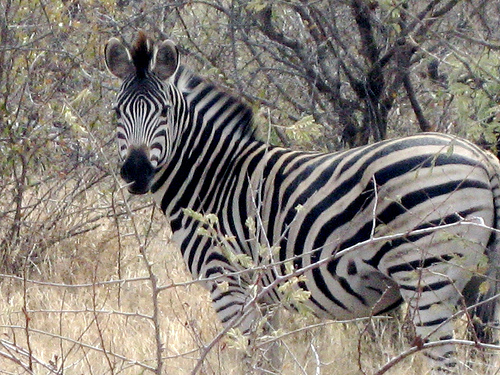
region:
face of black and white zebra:
[88, 37, 201, 216]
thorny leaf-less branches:
[48, 197, 161, 347]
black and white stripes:
[291, 153, 363, 228]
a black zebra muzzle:
[108, 138, 160, 204]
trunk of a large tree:
[283, 5, 410, 152]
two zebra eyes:
[108, 97, 184, 129]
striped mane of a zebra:
[181, 65, 267, 145]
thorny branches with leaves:
[188, 200, 308, 358]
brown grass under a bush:
[33, 213, 133, 295]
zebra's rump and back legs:
[366, 125, 495, 363]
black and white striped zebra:
[101, 35, 498, 369]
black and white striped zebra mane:
[130, 32, 257, 136]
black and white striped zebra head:
[113, 70, 178, 187]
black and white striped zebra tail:
[483, 157, 498, 274]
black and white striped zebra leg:
[196, 262, 262, 374]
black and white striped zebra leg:
[386, 200, 486, 368]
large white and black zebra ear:
[105, 37, 133, 79]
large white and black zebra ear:
[153, 40, 180, 81]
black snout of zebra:
[119, 149, 154, 192]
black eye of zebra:
[159, 104, 171, 117]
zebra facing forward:
[78, 23, 494, 370]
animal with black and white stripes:
[65, 24, 492, 366]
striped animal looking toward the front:
[55, 17, 492, 364]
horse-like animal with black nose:
[70, 22, 498, 362]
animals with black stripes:
[56, 22, 498, 351]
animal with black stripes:
[78, 27, 481, 372]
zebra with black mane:
[84, 27, 494, 367]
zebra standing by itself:
[79, 25, 496, 361]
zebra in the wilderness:
[62, 31, 499, 362]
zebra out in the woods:
[65, 31, 488, 372]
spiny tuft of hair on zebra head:
[130, 32, 165, 76]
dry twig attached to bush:
[128, 261, 200, 326]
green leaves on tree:
[54, 6, 75, 33]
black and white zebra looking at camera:
[91, 24, 494, 351]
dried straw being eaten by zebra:
[120, 155, 165, 197]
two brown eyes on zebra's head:
[112, 99, 173, 131]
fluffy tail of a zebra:
[480, 240, 498, 334]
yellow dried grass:
[126, 326, 159, 353]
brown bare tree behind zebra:
[291, 9, 415, 129]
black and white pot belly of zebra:
[290, 269, 388, 323]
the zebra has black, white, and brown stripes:
[78, 31, 498, 370]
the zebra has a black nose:
[95, 32, 197, 207]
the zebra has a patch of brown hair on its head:
[93, 19, 185, 101]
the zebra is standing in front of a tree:
[86, 0, 491, 370]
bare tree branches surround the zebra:
[1, 0, 497, 371]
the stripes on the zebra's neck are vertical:
[152, 55, 278, 315]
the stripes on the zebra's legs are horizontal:
[167, 156, 483, 372]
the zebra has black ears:
[95, 25, 190, 110]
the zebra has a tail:
[453, 131, 498, 287]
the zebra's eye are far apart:
[107, 91, 174, 133]